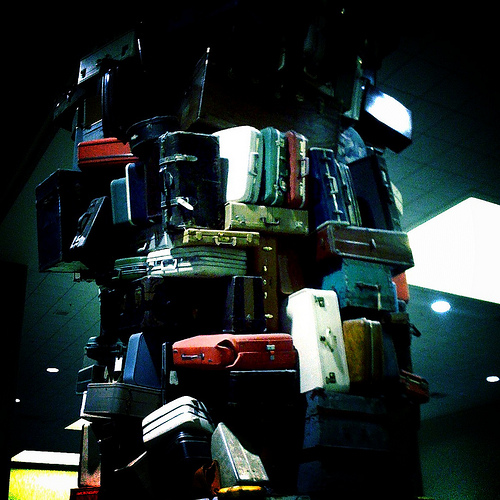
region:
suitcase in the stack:
[296, 290, 348, 390]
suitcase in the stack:
[232, 334, 286, 362]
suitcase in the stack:
[240, 129, 256, 203]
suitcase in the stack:
[307, 243, 410, 263]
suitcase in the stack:
[315, 153, 347, 220]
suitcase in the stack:
[176, 135, 221, 220]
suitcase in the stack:
[145, 249, 245, 272]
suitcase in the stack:
[72, 138, 144, 161]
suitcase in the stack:
[353, 95, 407, 139]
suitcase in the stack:
[193, 229, 259, 243]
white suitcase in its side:
[284, 284, 353, 405]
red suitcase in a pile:
[165, 327, 301, 379]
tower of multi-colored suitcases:
[39, 22, 448, 481]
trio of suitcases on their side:
[220, 117, 312, 213]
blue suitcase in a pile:
[74, 376, 166, 421]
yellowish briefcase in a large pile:
[179, 217, 266, 255]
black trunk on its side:
[153, 120, 233, 242]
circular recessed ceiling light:
[422, 290, 464, 331]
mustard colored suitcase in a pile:
[339, 308, 390, 403]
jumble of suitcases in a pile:
[79, 345, 264, 468]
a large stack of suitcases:
[31, 0, 444, 496]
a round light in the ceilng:
[430, 292, 454, 317]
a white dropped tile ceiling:
[18, 281, 92, 386]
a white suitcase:
[277, 286, 361, 402]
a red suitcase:
[167, 322, 300, 374]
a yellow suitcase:
[341, 313, 388, 400]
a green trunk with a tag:
[320, 253, 412, 320]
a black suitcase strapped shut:
[156, 122, 230, 240]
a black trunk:
[30, 164, 98, 277]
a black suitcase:
[172, 274, 278, 344]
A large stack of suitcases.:
[21, 22, 469, 498]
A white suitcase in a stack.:
[280, 269, 348, 399]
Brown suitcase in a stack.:
[251, 235, 279, 328]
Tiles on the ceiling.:
[40, 290, 90, 365]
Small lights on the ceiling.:
[28, 355, 68, 384]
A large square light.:
[398, 190, 499, 309]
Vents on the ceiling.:
[46, 298, 76, 325]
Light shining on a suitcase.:
[362, 80, 422, 152]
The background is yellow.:
[7, 462, 86, 499]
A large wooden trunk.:
[196, 46, 352, 153]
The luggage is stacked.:
[65, 51, 425, 488]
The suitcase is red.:
[172, 312, 293, 378]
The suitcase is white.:
[288, 278, 350, 399]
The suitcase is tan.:
[208, 194, 314, 234]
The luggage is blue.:
[109, 333, 180, 394]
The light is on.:
[395, 173, 498, 323]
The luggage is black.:
[300, 372, 409, 497]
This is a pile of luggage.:
[57, 9, 432, 498]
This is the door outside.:
[4, 446, 92, 499]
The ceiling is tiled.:
[400, 142, 471, 209]